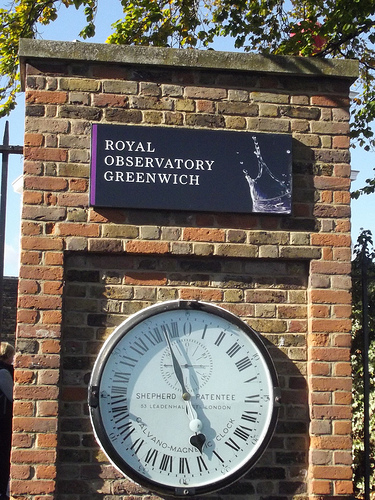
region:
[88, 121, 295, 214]
a sign for the Royal Observatory Greenwich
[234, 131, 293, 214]
an image of water splashing out of a cup on the sign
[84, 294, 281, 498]
a clock with a white face and black border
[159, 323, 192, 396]
the minute hand of the clock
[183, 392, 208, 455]
the hour hand of the clock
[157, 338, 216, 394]
an area of the clock for calculating seconds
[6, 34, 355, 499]
a brick structure with a clock on it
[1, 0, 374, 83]
tree branches above the brick structure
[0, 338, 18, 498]
a person standing behind the clock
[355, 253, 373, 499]
a black iron bar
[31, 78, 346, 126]
red brick wall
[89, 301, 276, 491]
clock with roman numeral numbers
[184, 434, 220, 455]
clock hand shaped as a spade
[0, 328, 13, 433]
partial view of a person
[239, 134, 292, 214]
water splashing on sign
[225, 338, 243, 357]
roman numeral number 3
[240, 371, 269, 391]
roman numeral number 5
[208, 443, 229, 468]
roman numeral number 10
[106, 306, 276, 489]
clock has white face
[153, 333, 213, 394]
a clock on the face of a clock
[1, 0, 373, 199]
Leafy green tree branches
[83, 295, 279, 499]
24 hour clock with Roman Numerals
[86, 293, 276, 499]
Black and white clock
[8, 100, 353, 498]
Brick clock tower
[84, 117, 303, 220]
Sign that says "Royal Observatory Greenwich"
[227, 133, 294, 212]
Splashing water logo on a sign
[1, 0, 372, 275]
Blue sky with partial clouds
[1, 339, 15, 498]
Person standing behind clock tower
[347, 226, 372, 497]
Metal fence post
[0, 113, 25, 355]
Spiky metal fence post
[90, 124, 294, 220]
royal observatory greenwich sign on brick structure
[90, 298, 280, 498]
clock on royal observatory greenwich sign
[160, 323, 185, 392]
minute hand on clock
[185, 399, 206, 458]
hour hand on clock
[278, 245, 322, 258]
brown brick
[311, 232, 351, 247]
orange brick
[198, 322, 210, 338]
clock with roman numerals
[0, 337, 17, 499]
person at royal observatory greenwich clock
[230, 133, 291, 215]
graphic of water drop on sign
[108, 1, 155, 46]
green foliage with beautiful day behind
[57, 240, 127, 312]
inset brick work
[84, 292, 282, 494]
face of a magnetic clock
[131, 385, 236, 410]
company name and address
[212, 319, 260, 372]
measurements in roman numerals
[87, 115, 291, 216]
sign for public display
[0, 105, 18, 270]
portion of a wrought iron fence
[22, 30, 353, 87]
concrete top to a brick marker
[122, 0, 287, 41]
hanging branches of a tree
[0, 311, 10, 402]
person on the other side of the fence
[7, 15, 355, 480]
gate of a famous observatory